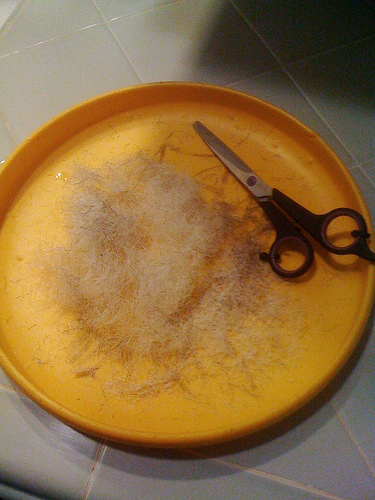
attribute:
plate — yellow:
[93, 82, 313, 259]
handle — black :
[255, 193, 363, 280]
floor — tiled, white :
[3, 2, 371, 497]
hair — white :
[74, 162, 258, 371]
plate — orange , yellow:
[1, 80, 367, 451]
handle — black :
[260, 183, 372, 272]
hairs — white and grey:
[68, 151, 267, 382]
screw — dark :
[247, 177, 257, 189]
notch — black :
[258, 248, 269, 262]